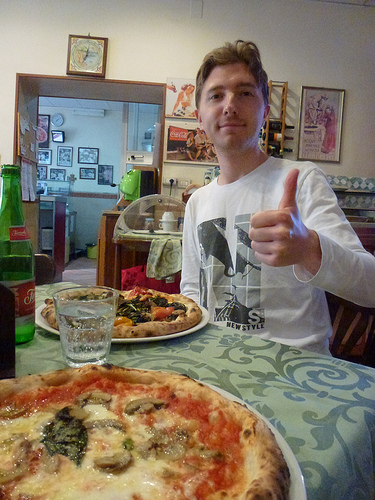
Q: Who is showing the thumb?
A: A man.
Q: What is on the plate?
A: Pizza.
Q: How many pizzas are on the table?
A: Two.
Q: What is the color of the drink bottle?
A: Green.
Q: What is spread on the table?
A: Tablecloth.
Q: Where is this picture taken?
A: Dining room.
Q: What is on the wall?
A: Picture frames and posters.